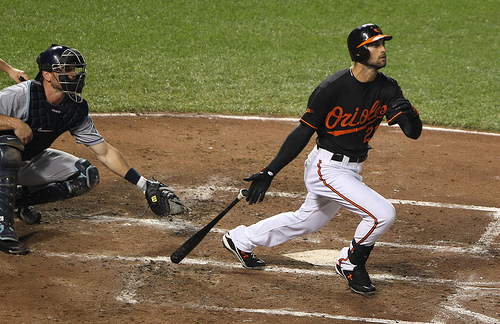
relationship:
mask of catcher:
[55, 45, 90, 106] [4, 40, 187, 257]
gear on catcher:
[10, 42, 104, 211] [4, 40, 187, 257]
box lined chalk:
[127, 110, 482, 321] [446, 233, 477, 256]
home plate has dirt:
[282, 244, 340, 269] [294, 243, 340, 263]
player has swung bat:
[216, 9, 442, 301] [166, 190, 249, 262]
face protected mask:
[51, 42, 90, 102] [55, 45, 90, 106]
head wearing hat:
[343, 18, 392, 61] [347, 22, 391, 62]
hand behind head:
[4, 56, 31, 87] [35, 42, 92, 103]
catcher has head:
[4, 40, 187, 257] [35, 42, 92, 103]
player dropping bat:
[216, 9, 442, 301] [166, 188, 252, 268]